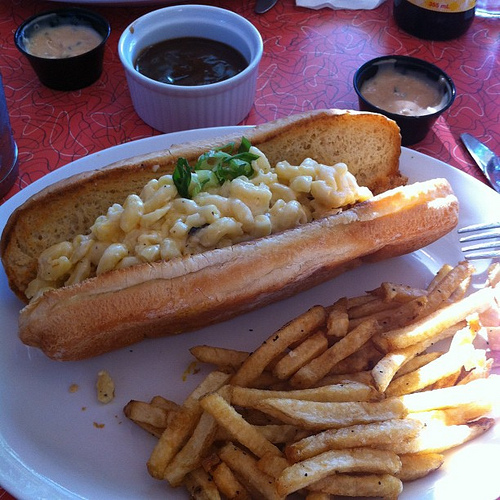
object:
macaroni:
[22, 145, 375, 309]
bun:
[1, 108, 457, 366]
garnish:
[168, 134, 262, 200]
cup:
[15, 10, 110, 95]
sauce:
[24, 18, 104, 60]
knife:
[458, 129, 500, 194]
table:
[2, 0, 500, 207]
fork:
[457, 220, 499, 260]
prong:
[458, 220, 500, 234]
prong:
[457, 230, 499, 243]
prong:
[461, 240, 500, 252]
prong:
[464, 249, 500, 261]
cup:
[117, 4, 264, 134]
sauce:
[132, 36, 250, 87]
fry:
[225, 304, 328, 388]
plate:
[0, 123, 499, 500]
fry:
[270, 330, 330, 381]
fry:
[288, 316, 383, 391]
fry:
[326, 296, 349, 337]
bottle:
[392, 0, 478, 40]